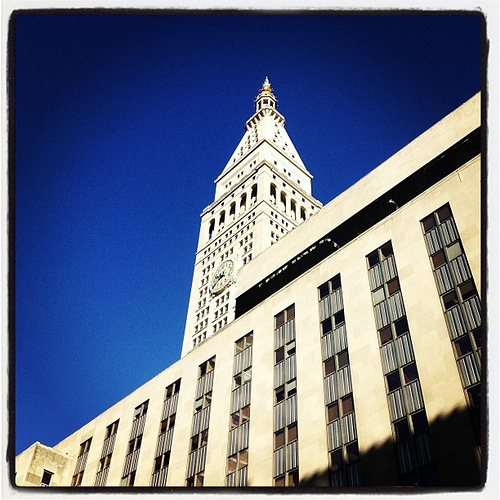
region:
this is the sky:
[37, 135, 134, 291]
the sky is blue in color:
[26, 132, 141, 353]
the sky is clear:
[31, 209, 113, 365]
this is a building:
[248, 79, 281, 477]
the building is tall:
[233, 74, 280, 481]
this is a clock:
[208, 258, 234, 293]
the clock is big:
[206, 250, 236, 295]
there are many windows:
[234, 332, 373, 433]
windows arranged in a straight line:
[272, 320, 297, 481]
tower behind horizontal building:
[105, 50, 416, 435]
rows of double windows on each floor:
[125, 260, 445, 461]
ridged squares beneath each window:
[315, 275, 360, 466]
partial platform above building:
[225, 155, 475, 316]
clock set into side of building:
[176, 235, 241, 300]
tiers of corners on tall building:
[235, 85, 295, 270]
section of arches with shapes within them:
[195, 160, 307, 232]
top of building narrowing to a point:
[210, 65, 320, 195]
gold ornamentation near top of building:
[250, 70, 293, 120]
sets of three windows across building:
[190, 220, 261, 340]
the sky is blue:
[35, 71, 180, 228]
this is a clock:
[192, 260, 247, 311]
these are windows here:
[220, 332, 295, 442]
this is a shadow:
[305, 417, 495, 470]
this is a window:
[30, 460, 60, 488]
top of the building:
[196, 72, 344, 267]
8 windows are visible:
[298, 282, 408, 334]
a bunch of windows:
[127, 405, 397, 495]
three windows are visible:
[230, 60, 282, 110]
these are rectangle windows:
[376, 367, 437, 405]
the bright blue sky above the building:
[8, 15, 490, 410]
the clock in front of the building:
[208, 255, 235, 296]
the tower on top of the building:
[185, 75, 323, 350]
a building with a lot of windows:
[14, 213, 487, 498]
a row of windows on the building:
[357, 235, 456, 497]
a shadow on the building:
[298, 405, 483, 491]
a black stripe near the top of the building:
[226, 87, 464, 320]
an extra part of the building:
[13, 440, 63, 495]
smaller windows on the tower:
[197, 300, 237, 334]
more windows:
[107, 419, 157, 499]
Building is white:
[16, 48, 492, 493]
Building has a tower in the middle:
[174, 52, 336, 359]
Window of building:
[270, 291, 302, 370]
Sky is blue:
[24, 16, 182, 351]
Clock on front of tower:
[207, 257, 240, 298]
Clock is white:
[202, 255, 240, 300]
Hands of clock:
[209, 271, 228, 289]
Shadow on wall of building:
[279, 403, 490, 497]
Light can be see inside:
[222, 444, 259, 486]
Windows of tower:
[198, 181, 310, 241]